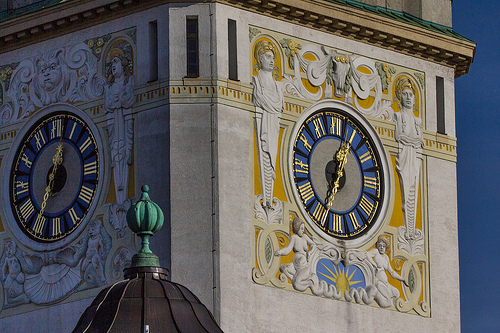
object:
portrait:
[244, 24, 439, 320]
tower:
[1, 0, 491, 333]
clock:
[285, 102, 391, 245]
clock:
[3, 106, 105, 246]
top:
[119, 180, 172, 275]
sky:
[452, 0, 500, 332]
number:
[328, 114, 344, 136]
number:
[348, 128, 358, 144]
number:
[357, 148, 375, 164]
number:
[361, 174, 380, 190]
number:
[356, 194, 377, 216]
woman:
[248, 39, 293, 213]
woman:
[388, 75, 432, 244]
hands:
[320, 141, 352, 223]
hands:
[32, 139, 67, 236]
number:
[348, 211, 361, 230]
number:
[331, 212, 344, 234]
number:
[311, 201, 332, 226]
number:
[297, 179, 316, 204]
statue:
[271, 214, 322, 293]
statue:
[364, 234, 413, 309]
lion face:
[28, 46, 74, 107]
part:
[62, 176, 234, 333]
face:
[283, 97, 401, 250]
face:
[0, 97, 117, 257]